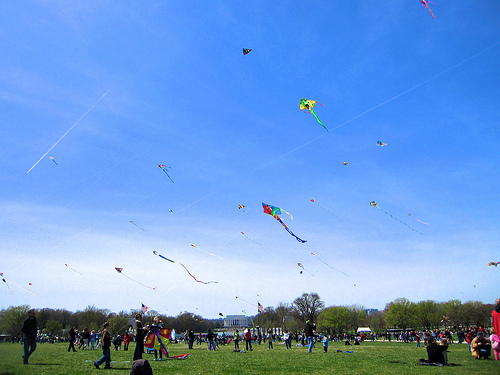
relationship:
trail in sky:
[174, 42, 499, 212] [3, 4, 498, 314]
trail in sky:
[24, 89, 111, 172] [3, 4, 498, 314]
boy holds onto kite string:
[90, 321, 116, 371] [146, 280, 221, 327]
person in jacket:
[466, 331, 497, 367] [469, 336, 483, 355]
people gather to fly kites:
[13, 297, 498, 372] [212, 78, 427, 267]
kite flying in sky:
[296, 97, 329, 132] [3, 4, 498, 314]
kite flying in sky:
[258, 201, 310, 251] [3, 4, 498, 314]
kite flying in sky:
[240, 46, 250, 57] [3, 4, 498, 314]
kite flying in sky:
[375, 139, 388, 151] [3, 4, 498, 314]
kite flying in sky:
[485, 261, 498, 269] [3, 4, 498, 314]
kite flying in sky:
[339, 158, 353, 171] [3, 4, 498, 314]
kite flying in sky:
[340, 187, 456, 249] [3, 4, 498, 314]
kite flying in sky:
[258, 197, 325, 264] [3, 4, 498, 314]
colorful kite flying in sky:
[262, 202, 308, 245] [3, 4, 498, 314]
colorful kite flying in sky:
[298, 97, 323, 126] [3, 4, 498, 314]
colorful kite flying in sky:
[157, 163, 174, 183] [3, 4, 498, 314]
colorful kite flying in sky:
[113, 266, 155, 290] [3, 4, 498, 314]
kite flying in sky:
[111, 220, 338, 298] [3, 4, 498, 314]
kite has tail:
[256, 191, 309, 241] [281, 224, 306, 244]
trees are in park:
[249, 280, 454, 362] [2, 118, 480, 369]